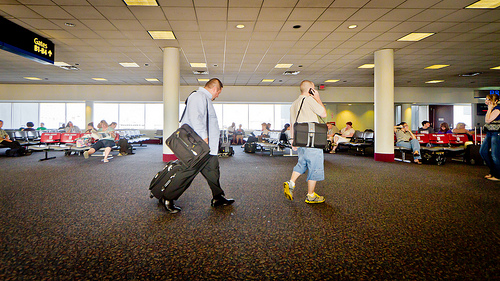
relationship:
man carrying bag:
[284, 80, 330, 204] [290, 94, 330, 153]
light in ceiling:
[234, 20, 246, 30] [2, 6, 498, 84]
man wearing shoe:
[157, 78, 235, 214] [154, 197, 184, 217]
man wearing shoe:
[157, 78, 235, 214] [208, 191, 239, 215]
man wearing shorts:
[284, 80, 330, 204] [285, 136, 329, 179]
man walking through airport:
[157, 78, 235, 214] [3, 5, 498, 277]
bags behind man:
[150, 154, 187, 201] [143, 73, 240, 223]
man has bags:
[143, 73, 240, 223] [150, 154, 187, 201]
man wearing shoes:
[143, 73, 240, 223] [277, 177, 332, 207]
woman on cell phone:
[480, 86, 500, 182] [307, 89, 317, 96]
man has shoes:
[157, 78, 235, 214] [154, 189, 240, 219]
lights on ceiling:
[396, 30, 436, 45] [2, 6, 498, 84]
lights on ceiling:
[424, 61, 450, 68] [2, 6, 498, 84]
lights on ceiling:
[358, 63, 375, 68] [2, 6, 498, 84]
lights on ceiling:
[147, 29, 178, 41] [2, 6, 498, 84]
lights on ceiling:
[123, 0, 160, 10] [2, 6, 498, 84]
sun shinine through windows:
[41, 98, 194, 152] [3, 86, 474, 152]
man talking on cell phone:
[284, 81, 330, 204] [304, 87, 317, 100]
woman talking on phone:
[475, 86, 500, 186] [483, 100, 485, 103]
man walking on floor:
[284, 80, 330, 204] [281, 194, 332, 221]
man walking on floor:
[157, 78, 235, 214] [3, 160, 485, 271]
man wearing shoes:
[284, 80, 330, 204] [280, 181, 326, 204]